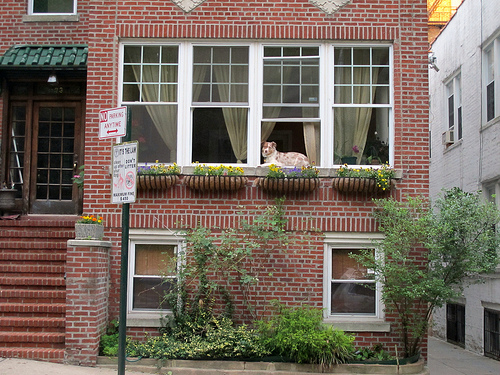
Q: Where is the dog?
A: On the window sill.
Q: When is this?
A: Daytime.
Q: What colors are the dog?
A: White and brown.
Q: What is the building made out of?
A: Brick.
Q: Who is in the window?
A: The dog.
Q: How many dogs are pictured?
A: One.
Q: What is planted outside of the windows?
A: Flowers.